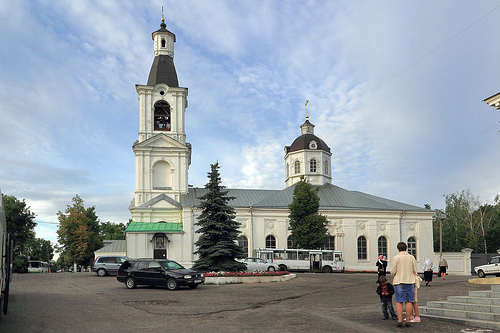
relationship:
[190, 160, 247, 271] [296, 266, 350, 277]
tree in driveway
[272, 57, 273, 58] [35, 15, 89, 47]
clouds in sky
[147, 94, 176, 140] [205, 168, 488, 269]
window of church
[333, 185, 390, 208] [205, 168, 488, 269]
roof of church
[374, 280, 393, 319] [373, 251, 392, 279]
boy with woman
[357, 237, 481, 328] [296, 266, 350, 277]
people on driveway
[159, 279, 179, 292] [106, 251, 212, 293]
tire on car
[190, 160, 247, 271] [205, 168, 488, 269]
tree next to church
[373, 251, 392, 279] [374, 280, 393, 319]
woman with boy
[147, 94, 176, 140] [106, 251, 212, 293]
window on car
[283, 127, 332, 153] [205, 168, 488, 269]
steeple on top of church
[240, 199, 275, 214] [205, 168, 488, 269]
awning on church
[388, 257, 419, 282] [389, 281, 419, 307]
man wearing shorts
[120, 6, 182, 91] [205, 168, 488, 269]
tower of church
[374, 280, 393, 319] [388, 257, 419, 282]
boy standing with man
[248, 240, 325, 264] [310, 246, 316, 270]
bus has door